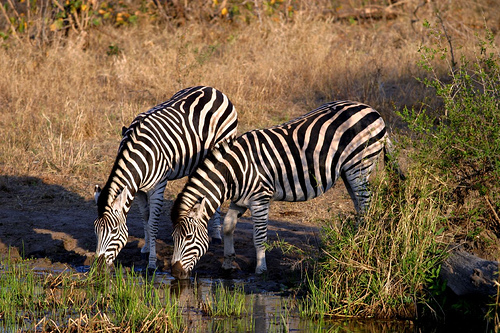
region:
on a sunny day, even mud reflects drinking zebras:
[92, 250, 294, 314]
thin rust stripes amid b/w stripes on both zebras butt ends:
[201, 90, 382, 181]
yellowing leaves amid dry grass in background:
[0, 0, 300, 37]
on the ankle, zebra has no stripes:
[251, 250, 268, 276]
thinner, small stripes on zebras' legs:
[135, 176, 371, 251]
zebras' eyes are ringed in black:
[107, 226, 193, 241]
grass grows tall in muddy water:
[0, 236, 295, 329]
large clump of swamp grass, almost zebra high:
[265, 146, 476, 321]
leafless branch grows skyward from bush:
[431, 3, 457, 71]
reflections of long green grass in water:
[202, 303, 357, 331]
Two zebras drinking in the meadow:
[74, 81, 419, 286]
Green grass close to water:
[0, 237, 481, 325]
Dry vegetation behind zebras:
[7, 10, 439, 205]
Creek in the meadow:
[24, 251, 331, 331]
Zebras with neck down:
[72, 68, 407, 303]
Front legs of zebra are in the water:
[218, 182, 276, 283]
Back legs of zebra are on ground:
[351, 177, 415, 277]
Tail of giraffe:
[374, 125, 405, 172]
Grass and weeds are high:
[315, 72, 497, 330]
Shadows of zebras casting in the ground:
[0, 181, 337, 266]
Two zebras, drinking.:
[93, 89, 406, 284]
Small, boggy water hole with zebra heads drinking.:
[32, 217, 325, 331]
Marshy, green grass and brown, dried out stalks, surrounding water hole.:
[4, 215, 451, 331]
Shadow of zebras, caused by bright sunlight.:
[2, 169, 407, 286]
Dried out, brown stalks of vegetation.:
[28, 42, 115, 164]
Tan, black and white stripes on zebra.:
[248, 137, 355, 179]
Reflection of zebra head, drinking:
[176, 281, 283, 331]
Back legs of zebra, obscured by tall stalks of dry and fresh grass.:
[335, 109, 443, 317]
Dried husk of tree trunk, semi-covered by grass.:
[438, 226, 496, 323]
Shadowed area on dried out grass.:
[335, 55, 496, 124]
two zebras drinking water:
[39, 61, 414, 288]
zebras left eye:
[104, 216, 121, 241]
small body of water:
[7, 247, 409, 332]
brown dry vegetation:
[14, 35, 346, 83]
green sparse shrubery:
[414, 46, 486, 153]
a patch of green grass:
[199, 277, 251, 322]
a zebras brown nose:
[164, 256, 191, 284]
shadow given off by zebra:
[5, 172, 88, 271]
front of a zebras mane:
[164, 188, 189, 229]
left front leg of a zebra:
[250, 201, 277, 281]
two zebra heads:
[91, 184, 211, 279]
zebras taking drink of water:
[36, 85, 392, 287]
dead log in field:
[438, 245, 498, 297]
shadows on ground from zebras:
[2, 175, 330, 301]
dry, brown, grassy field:
[1, 1, 498, 332]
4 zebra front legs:
[137, 181, 269, 276]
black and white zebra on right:
[173, 101, 395, 275]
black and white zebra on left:
[90, 85, 237, 273]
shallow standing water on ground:
[1, 256, 476, 332]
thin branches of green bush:
[381, 19, 498, 181]